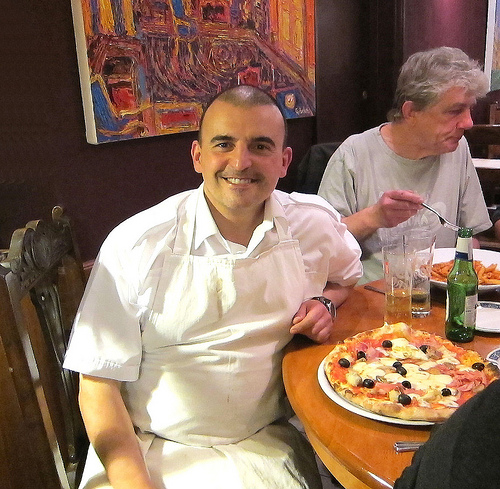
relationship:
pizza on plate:
[360, 332, 457, 407] [315, 326, 482, 437]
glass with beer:
[382, 230, 414, 329] [383, 291, 413, 326]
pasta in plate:
[419, 258, 499, 284] [410, 246, 499, 293]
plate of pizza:
[318, 326, 484, 417] [317, 313, 480, 430]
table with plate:
[345, 426, 407, 480] [318, 326, 484, 417]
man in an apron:
[126, 73, 326, 372] [106, 204, 335, 446]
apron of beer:
[78, 187, 323, 487] [383, 280, 415, 327]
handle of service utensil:
[392, 438, 427, 453] [392, 437, 433, 452]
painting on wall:
[68, 2, 320, 140] [315, 0, 394, 111]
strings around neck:
[139, 189, 214, 254] [202, 208, 262, 234]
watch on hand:
[310, 296, 338, 317] [288, 297, 329, 340]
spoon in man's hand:
[409, 188, 498, 256] [376, 189, 422, 228]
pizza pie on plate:
[336, 347, 428, 413] [319, 372, 351, 412]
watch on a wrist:
[310, 292, 338, 317] [301, 284, 344, 312]